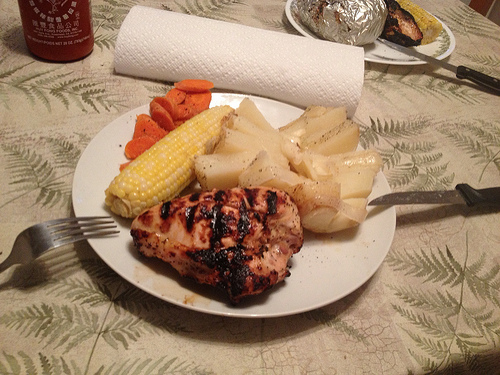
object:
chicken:
[153, 196, 293, 279]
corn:
[105, 103, 233, 217]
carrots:
[120, 77, 213, 158]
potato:
[275, 125, 351, 208]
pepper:
[255, 165, 272, 177]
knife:
[365, 188, 499, 210]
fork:
[49, 212, 120, 252]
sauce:
[19, 0, 96, 63]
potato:
[315, 7, 366, 33]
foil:
[355, 11, 372, 34]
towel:
[156, 27, 305, 82]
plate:
[87, 156, 110, 192]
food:
[98, 79, 383, 308]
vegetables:
[120, 78, 218, 170]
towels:
[120, 20, 353, 100]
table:
[381, 84, 471, 175]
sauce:
[208, 211, 227, 248]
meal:
[132, 123, 255, 207]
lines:
[196, 54, 240, 81]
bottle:
[17, 1, 97, 65]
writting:
[53, 21, 79, 31]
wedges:
[294, 115, 351, 159]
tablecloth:
[0, 79, 55, 217]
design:
[21, 74, 100, 109]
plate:
[380, 44, 450, 66]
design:
[433, 41, 449, 58]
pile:
[154, 87, 181, 119]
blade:
[385, 46, 458, 76]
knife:
[378, 39, 499, 98]